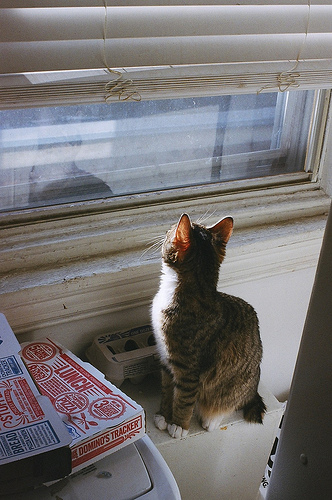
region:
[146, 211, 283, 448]
grey striped cat looking out a window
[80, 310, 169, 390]
part of an egg carton can be seen behind the cat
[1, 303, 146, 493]
Domino's pizza boxes in foreground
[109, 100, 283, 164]
window is dirty with white specks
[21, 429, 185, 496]
trash receptacle under pizza boxes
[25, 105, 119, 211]
Reflection of the cat can be seen in the window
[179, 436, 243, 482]
cat is on top of a white cabinet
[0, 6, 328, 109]
white blinds in window are partially open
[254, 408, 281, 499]
part of a printed message can be seen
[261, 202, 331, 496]
part of a cabinet or door on right side of frame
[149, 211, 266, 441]
a tabby cat looks up at a window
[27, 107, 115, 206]
the cat's image is reflected in the window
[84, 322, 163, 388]
an empty egg carton is near the cat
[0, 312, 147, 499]
two empty pizza boxes at atop a trash can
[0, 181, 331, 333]
the white window sill is dirty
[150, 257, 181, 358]
the cat's chest is white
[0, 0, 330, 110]
white window blinds are raised halfway up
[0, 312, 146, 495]
the pizza boxes are from Domino's Pizza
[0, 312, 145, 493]
the pizza boxes are red, white, and blue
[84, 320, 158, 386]
the empty egg carton is made of cardboard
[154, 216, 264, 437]
brown black and white cat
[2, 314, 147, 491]
red white and blue pizza boxes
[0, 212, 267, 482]
cat sitting next to pizza boxes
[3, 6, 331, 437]
cat looking out the window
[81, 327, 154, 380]
gray and blue egg carton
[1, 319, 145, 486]
red lettering on white boxes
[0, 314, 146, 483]
blue lettering on white boxes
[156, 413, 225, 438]
cat's white feet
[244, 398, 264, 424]
cat's brown and black tail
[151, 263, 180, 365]
cat's white chest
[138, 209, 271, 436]
a cat in a sitting posture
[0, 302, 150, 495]
couple of pizza boxes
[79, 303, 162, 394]
an egg carton box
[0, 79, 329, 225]
a window of a inside building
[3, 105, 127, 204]
a window reflection of cat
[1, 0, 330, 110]
blind of a window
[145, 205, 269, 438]
a cat looking up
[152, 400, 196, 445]
paws of a cat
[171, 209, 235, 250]
ear of a cat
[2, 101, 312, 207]
reflections of a window